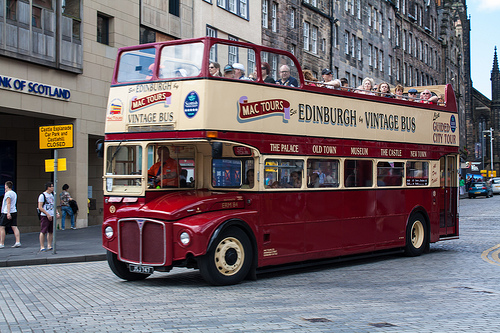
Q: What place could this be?
A: It is a city.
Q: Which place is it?
A: It is a city.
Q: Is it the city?
A: Yes, it is the city.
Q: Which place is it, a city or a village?
A: It is a city.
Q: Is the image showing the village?
A: No, the picture is showing the city.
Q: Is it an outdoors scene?
A: Yes, it is outdoors.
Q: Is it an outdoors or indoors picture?
A: It is outdoors.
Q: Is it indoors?
A: No, it is outdoors.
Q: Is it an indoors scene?
A: No, it is outdoors.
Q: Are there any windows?
A: Yes, there is a window.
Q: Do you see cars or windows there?
A: Yes, there is a window.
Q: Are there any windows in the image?
A: Yes, there is a window.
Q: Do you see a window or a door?
A: Yes, there is a window.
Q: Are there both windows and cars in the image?
A: Yes, there are both a window and a car.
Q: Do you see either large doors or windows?
A: Yes, there is a large window.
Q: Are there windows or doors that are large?
A: Yes, the window is large.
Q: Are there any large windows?
A: Yes, there is a large window.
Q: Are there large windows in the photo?
A: Yes, there is a large window.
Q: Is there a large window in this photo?
A: Yes, there is a large window.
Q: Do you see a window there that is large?
A: Yes, there is a window that is large.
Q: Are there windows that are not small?
A: Yes, there is a large window.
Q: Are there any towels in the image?
A: No, there are no towels.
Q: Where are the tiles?
A: The tiles are on the street.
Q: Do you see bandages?
A: No, there are no bandages.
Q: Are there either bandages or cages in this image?
A: No, there are no bandages or cages.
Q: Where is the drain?
A: The drain is on the street.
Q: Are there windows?
A: Yes, there are windows.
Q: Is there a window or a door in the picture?
A: Yes, there are windows.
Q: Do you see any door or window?
A: Yes, there are windows.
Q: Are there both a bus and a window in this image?
A: Yes, there are both a window and a bus.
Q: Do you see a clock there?
A: No, there are no clocks.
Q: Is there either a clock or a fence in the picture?
A: No, there are no clocks or fences.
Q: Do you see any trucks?
A: No, there are no trucks.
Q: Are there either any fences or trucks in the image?
A: No, there are no trucks or fences.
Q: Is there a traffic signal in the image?
A: No, there are no traffic lights.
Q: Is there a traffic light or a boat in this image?
A: No, there are no traffic lights or boats.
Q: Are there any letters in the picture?
A: Yes, there are letters.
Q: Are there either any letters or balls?
A: Yes, there are letters.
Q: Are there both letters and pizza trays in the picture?
A: No, there are letters but no pizza trays.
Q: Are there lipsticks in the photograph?
A: No, there are no lipsticks.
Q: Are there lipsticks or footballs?
A: No, there are no lipsticks or footballs.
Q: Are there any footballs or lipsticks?
A: No, there are no lipsticks or footballs.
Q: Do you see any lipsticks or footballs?
A: No, there are no lipsticks or footballs.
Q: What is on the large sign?
A: The letters are on the sign.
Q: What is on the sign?
A: The letters are on the sign.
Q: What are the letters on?
A: The letters are on the sign.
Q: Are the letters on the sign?
A: Yes, the letters are on the sign.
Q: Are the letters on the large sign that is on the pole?
A: Yes, the letters are on the sign.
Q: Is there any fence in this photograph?
A: No, there are no fences.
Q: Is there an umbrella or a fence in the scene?
A: No, there are no fences or umbrellas.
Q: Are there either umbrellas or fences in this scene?
A: No, there are no fences or umbrellas.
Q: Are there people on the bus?
A: Yes, there are people on the bus.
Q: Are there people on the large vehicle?
A: Yes, there are people on the bus.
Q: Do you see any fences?
A: No, there are no fences.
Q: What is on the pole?
A: The sign is on the pole.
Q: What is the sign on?
A: The sign is on the pole.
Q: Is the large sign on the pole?
A: Yes, the sign is on the pole.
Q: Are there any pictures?
A: No, there are no pictures.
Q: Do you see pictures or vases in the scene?
A: No, there are no pictures or vases.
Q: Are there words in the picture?
A: Yes, there are words.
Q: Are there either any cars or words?
A: Yes, there are words.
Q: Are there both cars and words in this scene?
A: Yes, there are both words and a car.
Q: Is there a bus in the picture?
A: Yes, there is a bus.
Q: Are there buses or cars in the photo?
A: Yes, there is a bus.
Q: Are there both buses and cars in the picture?
A: Yes, there are both a bus and a car.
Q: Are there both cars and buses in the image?
A: Yes, there are both a bus and a car.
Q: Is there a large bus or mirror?
A: Yes, there is a large bus.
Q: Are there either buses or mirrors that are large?
A: Yes, the bus is large.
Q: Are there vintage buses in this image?
A: Yes, there is a vintage bus.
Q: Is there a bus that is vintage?
A: Yes, there is a bus that is vintage.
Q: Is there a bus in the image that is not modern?
A: Yes, there is a vintage bus.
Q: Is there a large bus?
A: Yes, there is a large bus.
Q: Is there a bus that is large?
A: Yes, there is a bus that is large.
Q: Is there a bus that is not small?
A: Yes, there is a large bus.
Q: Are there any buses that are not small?
A: Yes, there is a large bus.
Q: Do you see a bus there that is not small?
A: Yes, there is a large bus.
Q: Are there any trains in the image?
A: No, there are no trains.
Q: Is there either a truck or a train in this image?
A: No, there are no trains or trucks.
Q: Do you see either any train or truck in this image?
A: No, there are no trains or trucks.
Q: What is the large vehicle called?
A: The vehicle is a bus.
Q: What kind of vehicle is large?
A: The vehicle is a bus.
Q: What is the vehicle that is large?
A: The vehicle is a bus.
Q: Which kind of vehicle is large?
A: The vehicle is a bus.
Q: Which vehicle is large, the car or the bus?
A: The bus is large.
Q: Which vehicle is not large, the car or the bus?
A: The car is not large.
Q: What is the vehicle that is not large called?
A: The vehicle is a car.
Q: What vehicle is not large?
A: The vehicle is a car.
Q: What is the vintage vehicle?
A: The vehicle is a bus.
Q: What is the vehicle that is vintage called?
A: The vehicle is a bus.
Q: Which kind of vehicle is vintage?
A: The vehicle is a bus.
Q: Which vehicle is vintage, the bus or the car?
A: The bus is vintage.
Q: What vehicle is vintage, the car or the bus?
A: The bus is vintage.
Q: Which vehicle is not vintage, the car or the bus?
A: The car is not vintage.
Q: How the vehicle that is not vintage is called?
A: The vehicle is a car.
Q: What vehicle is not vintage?
A: The vehicle is a car.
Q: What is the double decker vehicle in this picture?
A: The vehicle is a bus.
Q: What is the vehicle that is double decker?
A: The vehicle is a bus.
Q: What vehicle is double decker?
A: The vehicle is a bus.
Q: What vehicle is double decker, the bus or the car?
A: The bus is double decker.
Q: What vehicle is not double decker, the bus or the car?
A: The car is not double decker.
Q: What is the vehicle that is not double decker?
A: The vehicle is a car.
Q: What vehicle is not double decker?
A: The vehicle is a car.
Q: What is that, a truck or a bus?
A: That is a bus.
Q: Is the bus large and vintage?
A: Yes, the bus is large and vintage.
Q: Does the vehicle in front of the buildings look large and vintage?
A: Yes, the bus is large and vintage.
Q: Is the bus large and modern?
A: No, the bus is large but vintage.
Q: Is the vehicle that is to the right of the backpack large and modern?
A: No, the bus is large but vintage.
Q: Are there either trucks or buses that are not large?
A: No, there is a bus but it is large.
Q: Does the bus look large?
A: Yes, the bus is large.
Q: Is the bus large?
A: Yes, the bus is large.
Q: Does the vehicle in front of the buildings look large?
A: Yes, the bus is large.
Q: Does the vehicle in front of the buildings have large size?
A: Yes, the bus is large.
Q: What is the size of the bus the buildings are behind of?
A: The bus is large.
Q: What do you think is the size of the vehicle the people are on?
A: The bus is large.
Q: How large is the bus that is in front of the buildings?
A: The bus is large.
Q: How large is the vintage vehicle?
A: The bus is large.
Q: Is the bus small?
A: No, the bus is large.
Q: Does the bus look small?
A: No, the bus is large.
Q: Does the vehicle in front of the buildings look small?
A: No, the bus is large.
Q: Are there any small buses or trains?
A: No, there is a bus but it is large.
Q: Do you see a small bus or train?
A: No, there is a bus but it is large.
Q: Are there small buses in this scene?
A: No, there is a bus but it is large.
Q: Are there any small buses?
A: No, there is a bus but it is large.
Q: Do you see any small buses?
A: No, there is a bus but it is large.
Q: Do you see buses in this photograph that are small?
A: No, there is a bus but it is large.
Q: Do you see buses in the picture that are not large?
A: No, there is a bus but it is large.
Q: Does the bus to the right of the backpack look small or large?
A: The bus is large.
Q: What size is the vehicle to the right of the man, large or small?
A: The bus is large.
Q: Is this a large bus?
A: Yes, this is a large bus.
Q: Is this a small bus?
A: No, this is a large bus.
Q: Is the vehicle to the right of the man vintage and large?
A: Yes, the bus is vintage and large.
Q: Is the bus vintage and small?
A: No, the bus is vintage but large.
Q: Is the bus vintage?
A: Yes, the bus is vintage.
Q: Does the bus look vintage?
A: Yes, the bus is vintage.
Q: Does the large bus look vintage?
A: Yes, the bus is vintage.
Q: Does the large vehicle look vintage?
A: Yes, the bus is vintage.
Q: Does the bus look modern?
A: No, the bus is vintage.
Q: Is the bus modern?
A: No, the bus is vintage.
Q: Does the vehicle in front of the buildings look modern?
A: No, the bus is vintage.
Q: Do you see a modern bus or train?
A: No, there is a bus but it is vintage.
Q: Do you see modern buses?
A: No, there is a bus but it is vintage.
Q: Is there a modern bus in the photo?
A: No, there is a bus but it is vintage.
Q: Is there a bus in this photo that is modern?
A: No, there is a bus but it is vintage.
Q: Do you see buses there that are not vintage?
A: No, there is a bus but it is vintage.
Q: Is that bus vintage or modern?
A: The bus is vintage.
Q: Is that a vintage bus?
A: Yes, that is a vintage bus.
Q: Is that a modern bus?
A: No, that is a vintage bus.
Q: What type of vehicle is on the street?
A: The vehicle is a bus.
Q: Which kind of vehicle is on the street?
A: The vehicle is a bus.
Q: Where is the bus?
A: The bus is on the street.